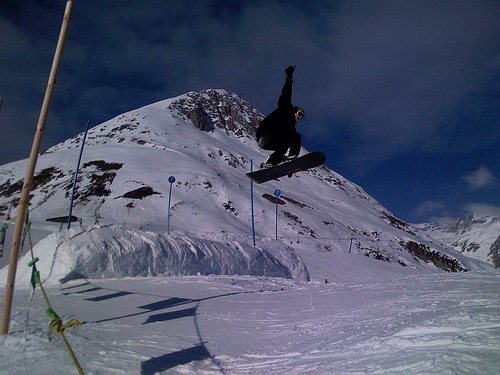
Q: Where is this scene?
A: Mountain.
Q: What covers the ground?
A: Snow.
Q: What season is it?
A: Winter.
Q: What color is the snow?
A: White.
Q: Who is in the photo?
A: A person.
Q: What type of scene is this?
A: Outdoor.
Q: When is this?
A: Daytime.